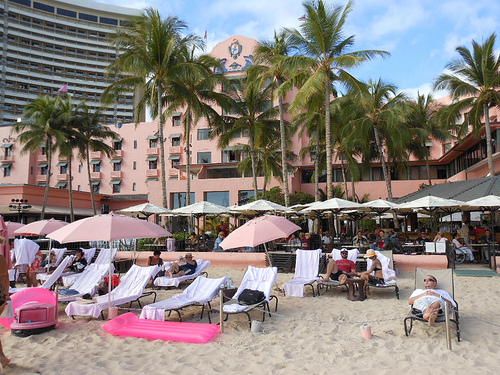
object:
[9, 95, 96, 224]
tree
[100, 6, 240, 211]
tree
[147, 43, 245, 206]
tree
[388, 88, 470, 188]
tree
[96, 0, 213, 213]
tree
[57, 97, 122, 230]
tree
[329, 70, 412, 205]
tree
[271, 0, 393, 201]
tree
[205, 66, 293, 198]
tree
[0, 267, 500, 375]
sand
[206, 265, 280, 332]
lounge chairs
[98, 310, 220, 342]
inflatable object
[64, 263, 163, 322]
chain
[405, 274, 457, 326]
man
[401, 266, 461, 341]
lounge chair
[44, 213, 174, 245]
umbrellas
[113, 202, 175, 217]
umbrellas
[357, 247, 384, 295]
woman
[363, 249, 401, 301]
lounge chair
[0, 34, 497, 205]
building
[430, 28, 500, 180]
palm trees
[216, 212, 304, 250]
umbrella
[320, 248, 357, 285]
people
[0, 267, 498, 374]
beach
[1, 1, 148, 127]
building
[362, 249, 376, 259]
hat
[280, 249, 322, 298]
beach towel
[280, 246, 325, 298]
chair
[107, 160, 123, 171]
windows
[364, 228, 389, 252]
people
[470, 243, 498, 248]
tables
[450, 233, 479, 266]
person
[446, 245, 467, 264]
wheelchair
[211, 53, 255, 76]
decoration